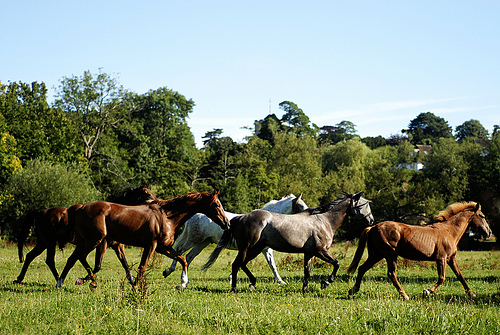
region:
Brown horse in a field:
[58, 196, 206, 316]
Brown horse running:
[24, 188, 177, 306]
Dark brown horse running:
[231, 171, 378, 333]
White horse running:
[174, 182, 338, 283]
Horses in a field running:
[36, 166, 486, 320]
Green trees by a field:
[21, 53, 366, 255]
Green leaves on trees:
[131, 76, 393, 250]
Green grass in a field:
[26, 264, 179, 332]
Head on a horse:
[430, 194, 498, 238]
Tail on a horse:
[212, 208, 259, 271]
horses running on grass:
[20, 165, 482, 328]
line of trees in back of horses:
[25, 70, 475, 231]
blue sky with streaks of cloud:
[216, 31, 466, 126]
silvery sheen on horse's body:
[235, 190, 347, 280]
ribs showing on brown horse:
[346, 195, 486, 300]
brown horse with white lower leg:
[60, 187, 221, 302]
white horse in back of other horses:
[160, 181, 330, 291]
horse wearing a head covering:
[305, 180, 375, 256]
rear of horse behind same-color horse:
[10, 185, 130, 290]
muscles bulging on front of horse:
[138, 190, 185, 251]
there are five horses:
[9, 161, 481, 303]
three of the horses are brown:
[24, 132, 499, 296]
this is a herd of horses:
[18, 146, 490, 303]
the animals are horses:
[12, 114, 497, 301]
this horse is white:
[140, 157, 368, 314]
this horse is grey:
[215, 185, 381, 306]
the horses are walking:
[6, 132, 491, 314]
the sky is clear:
[48, 25, 243, 124]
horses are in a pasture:
[20, 120, 495, 295]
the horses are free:
[10, 105, 497, 324]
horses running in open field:
[12, 149, 492, 313]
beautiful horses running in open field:
[11, 157, 487, 313]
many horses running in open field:
[14, 136, 491, 314]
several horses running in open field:
[8, 149, 489, 314]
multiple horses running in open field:
[1, 138, 488, 313]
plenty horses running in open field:
[15, 120, 492, 320]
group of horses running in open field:
[11, 115, 491, 309]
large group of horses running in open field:
[6, 135, 491, 324]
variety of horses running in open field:
[9, 136, 491, 313]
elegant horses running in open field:
[7, 154, 490, 324]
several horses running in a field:
[15, 177, 483, 306]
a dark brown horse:
[48, 184, 228, 275]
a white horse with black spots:
[172, 186, 304, 264]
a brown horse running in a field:
[357, 192, 489, 305]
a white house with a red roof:
[379, 102, 474, 192]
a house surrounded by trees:
[340, 122, 465, 210]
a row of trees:
[30, 107, 431, 207]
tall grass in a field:
[50, 290, 379, 332]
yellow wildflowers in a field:
[92, 297, 115, 324]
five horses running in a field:
[1, 185, 486, 315]